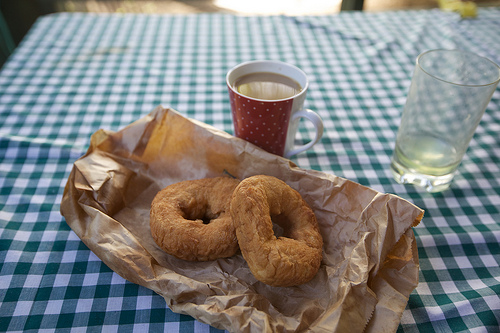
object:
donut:
[228, 173, 325, 288]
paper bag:
[58, 104, 426, 333]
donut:
[148, 175, 243, 263]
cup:
[225, 59, 325, 160]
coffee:
[233, 71, 302, 100]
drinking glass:
[388, 48, 500, 195]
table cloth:
[0, 6, 500, 333]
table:
[0, 7, 500, 333]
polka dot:
[262, 122, 266, 126]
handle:
[286, 106, 324, 155]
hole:
[269, 212, 296, 239]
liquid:
[393, 131, 463, 177]